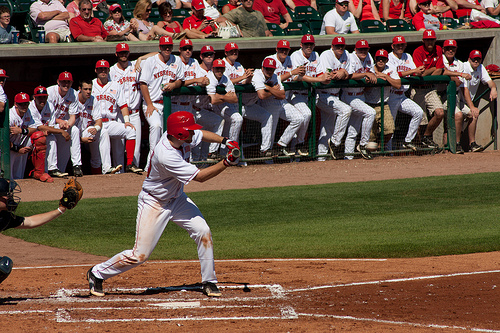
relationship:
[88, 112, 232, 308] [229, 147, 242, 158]
batter holding bat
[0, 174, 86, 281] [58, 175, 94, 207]
catcher wears catchers mitt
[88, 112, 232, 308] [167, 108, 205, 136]
batter has red helmet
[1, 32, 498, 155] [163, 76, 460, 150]
dugout behind fence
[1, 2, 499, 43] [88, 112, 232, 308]
audience watches batter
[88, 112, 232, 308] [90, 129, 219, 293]
batter wears uniform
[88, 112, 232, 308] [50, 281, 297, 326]
batter standing on home plate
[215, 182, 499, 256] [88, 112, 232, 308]
grass beside batter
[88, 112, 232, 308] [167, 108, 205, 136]
batter wearing helmet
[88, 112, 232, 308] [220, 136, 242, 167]
batter wearing gloves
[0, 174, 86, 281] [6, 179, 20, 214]
catcher wearing faceguard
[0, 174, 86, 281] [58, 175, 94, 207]
catcher wearing mitt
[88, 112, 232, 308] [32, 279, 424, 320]
batter standing in dirt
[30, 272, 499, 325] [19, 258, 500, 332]
chalk lines are in dirt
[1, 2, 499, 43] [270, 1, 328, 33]
spectators are sitting in bleachers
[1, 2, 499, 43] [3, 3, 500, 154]
spectators are on sidelines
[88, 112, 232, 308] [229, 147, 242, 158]
batter has bat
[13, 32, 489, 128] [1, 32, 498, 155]
players are in dugout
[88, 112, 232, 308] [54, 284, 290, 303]
batter standing on batter box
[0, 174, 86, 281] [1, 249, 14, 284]
catcher has leg guards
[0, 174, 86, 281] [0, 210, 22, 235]
catcher wearing black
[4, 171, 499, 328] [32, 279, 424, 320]
baseball field has dirt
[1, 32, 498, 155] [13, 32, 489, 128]
dugout full of teammates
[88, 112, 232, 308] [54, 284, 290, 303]
batter stands in batter box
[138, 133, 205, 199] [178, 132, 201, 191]
jersey has short sleeves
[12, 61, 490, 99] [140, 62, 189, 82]
shirts have short sleeves